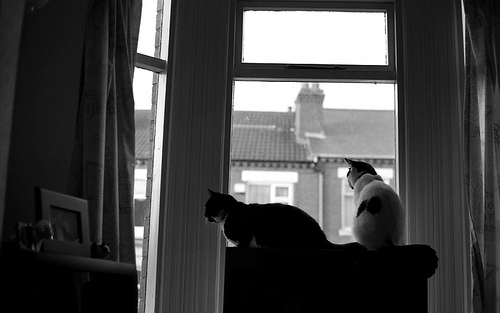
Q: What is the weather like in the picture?
A: It is overcast.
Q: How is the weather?
A: It is overcast.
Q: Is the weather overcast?
A: Yes, it is overcast.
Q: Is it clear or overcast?
A: It is overcast.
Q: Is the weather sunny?
A: No, it is overcast.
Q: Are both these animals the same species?
A: Yes, all the animals are cats.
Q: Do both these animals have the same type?
A: Yes, all the animals are cats.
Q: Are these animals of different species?
A: No, all the animals are cats.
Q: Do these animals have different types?
A: No, all the animals are cats.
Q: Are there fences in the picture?
A: No, there are no fences.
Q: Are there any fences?
A: No, there are no fences.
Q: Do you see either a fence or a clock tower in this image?
A: No, there are no fences or clock towers.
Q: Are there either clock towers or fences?
A: No, there are no fences or clock towers.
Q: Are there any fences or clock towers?
A: No, there are no fences or clock towers.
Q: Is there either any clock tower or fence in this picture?
A: No, there are no fences or clock towers.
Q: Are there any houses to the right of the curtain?
A: Yes, there is a house to the right of the curtain.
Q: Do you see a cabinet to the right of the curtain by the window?
A: No, there is a house to the right of the curtain.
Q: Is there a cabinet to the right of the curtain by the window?
A: No, there is a house to the right of the curtain.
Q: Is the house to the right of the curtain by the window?
A: Yes, the house is to the right of the curtain.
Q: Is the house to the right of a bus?
A: No, the house is to the right of the curtain.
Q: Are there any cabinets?
A: No, there are no cabinets.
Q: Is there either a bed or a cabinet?
A: No, there are no cabinets or beds.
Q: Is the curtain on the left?
A: Yes, the curtain is on the left of the image.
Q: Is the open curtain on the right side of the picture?
A: No, the curtain is on the left of the image.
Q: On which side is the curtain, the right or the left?
A: The curtain is on the left of the image.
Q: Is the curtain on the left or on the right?
A: The curtain is on the left of the image.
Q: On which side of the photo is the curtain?
A: The curtain is on the left of the image.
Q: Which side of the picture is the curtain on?
A: The curtain is on the left of the image.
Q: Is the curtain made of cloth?
A: Yes, the curtain is made of cloth.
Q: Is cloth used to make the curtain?
A: Yes, the curtain is made of cloth.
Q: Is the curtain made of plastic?
A: No, the curtain is made of cloth.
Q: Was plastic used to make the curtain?
A: No, the curtain is made of cloth.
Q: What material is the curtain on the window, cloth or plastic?
A: The curtain is made of cloth.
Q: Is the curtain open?
A: Yes, the curtain is open.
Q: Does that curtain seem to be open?
A: Yes, the curtain is open.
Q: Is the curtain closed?
A: No, the curtain is open.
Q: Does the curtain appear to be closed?
A: No, the curtain is open.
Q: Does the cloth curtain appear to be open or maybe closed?
A: The curtain is open.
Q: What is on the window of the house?
A: The curtain is on the window.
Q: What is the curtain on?
A: The curtain is on the window.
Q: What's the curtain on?
A: The curtain is on the window.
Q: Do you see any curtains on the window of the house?
A: Yes, there is a curtain on the window.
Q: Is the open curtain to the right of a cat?
A: No, the curtain is to the left of a cat.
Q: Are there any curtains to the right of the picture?
A: Yes, there is a curtain to the right of the picture.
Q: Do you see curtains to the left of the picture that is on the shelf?
A: No, the curtain is to the right of the picture.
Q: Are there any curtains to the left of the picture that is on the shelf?
A: No, the curtain is to the right of the picture.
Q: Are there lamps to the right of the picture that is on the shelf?
A: No, there is a curtain to the right of the picture.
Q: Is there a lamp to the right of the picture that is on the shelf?
A: No, there is a curtain to the right of the picture.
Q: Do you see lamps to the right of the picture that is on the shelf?
A: No, there is a curtain to the right of the picture.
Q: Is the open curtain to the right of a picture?
A: Yes, the curtain is to the right of a picture.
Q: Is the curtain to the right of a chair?
A: No, the curtain is to the right of a picture.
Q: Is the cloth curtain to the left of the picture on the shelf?
A: No, the curtain is to the right of the picture.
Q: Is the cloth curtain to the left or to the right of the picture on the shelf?
A: The curtain is to the right of the picture.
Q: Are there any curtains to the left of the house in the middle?
A: Yes, there is a curtain to the left of the house.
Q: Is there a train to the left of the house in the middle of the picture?
A: No, there is a curtain to the left of the house.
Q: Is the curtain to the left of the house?
A: Yes, the curtain is to the left of the house.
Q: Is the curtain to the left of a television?
A: No, the curtain is to the left of the house.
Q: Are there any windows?
A: Yes, there is a window.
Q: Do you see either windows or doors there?
A: Yes, there is a window.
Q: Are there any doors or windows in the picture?
A: Yes, there is a window.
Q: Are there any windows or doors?
A: Yes, there is a window.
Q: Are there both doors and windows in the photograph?
A: No, there is a window but no doors.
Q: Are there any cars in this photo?
A: No, there are no cars.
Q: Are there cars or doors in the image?
A: No, there are no cars or doors.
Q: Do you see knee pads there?
A: No, there are no knee pads.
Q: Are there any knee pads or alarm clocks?
A: No, there are no knee pads or alarm clocks.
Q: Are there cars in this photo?
A: No, there are no cars.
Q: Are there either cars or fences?
A: No, there are no cars or fences.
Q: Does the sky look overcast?
A: Yes, the sky is overcast.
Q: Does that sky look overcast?
A: Yes, the sky is overcast.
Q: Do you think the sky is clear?
A: No, the sky is overcast.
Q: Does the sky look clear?
A: No, the sky is overcast.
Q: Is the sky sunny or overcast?
A: The sky is overcast.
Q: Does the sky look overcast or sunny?
A: The sky is overcast.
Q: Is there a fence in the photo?
A: No, there are no fences.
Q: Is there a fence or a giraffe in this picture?
A: No, there are no fences or giraffes.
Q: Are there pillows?
A: No, there are no pillows.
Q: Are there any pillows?
A: No, there are no pillows.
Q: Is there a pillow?
A: No, there are no pillows.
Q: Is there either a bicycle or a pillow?
A: No, there are no pillows or bicycles.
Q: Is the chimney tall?
A: Yes, the chimney is tall.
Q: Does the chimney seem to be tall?
A: Yes, the chimney is tall.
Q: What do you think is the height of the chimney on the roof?
A: The chimney is tall.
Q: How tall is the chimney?
A: The chimney is tall.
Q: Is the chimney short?
A: No, the chimney is tall.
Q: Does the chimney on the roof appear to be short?
A: No, the chimney is tall.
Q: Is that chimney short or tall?
A: The chimney is tall.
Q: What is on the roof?
A: The chimney is on the roof.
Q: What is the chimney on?
A: The chimney is on the roof.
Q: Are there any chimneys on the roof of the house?
A: Yes, there is a chimney on the roof.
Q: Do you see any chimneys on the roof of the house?
A: Yes, there is a chimney on the roof.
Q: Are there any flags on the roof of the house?
A: No, there is a chimney on the roof.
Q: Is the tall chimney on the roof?
A: Yes, the chimney is on the roof.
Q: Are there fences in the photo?
A: No, there are no fences.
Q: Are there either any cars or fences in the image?
A: No, there are no fences or cars.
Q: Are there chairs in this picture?
A: No, there are no chairs.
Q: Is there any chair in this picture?
A: No, there are no chairs.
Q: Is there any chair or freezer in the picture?
A: No, there are no chairs or refrigerators.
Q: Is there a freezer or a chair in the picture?
A: No, there are no chairs or refrigerators.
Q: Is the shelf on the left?
A: Yes, the shelf is on the left of the image.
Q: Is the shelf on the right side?
A: No, the shelf is on the left of the image.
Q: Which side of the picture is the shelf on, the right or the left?
A: The shelf is on the left of the image.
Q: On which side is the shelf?
A: The shelf is on the left of the image.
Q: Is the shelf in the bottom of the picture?
A: Yes, the shelf is in the bottom of the image.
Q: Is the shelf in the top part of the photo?
A: No, the shelf is in the bottom of the image.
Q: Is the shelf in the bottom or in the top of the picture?
A: The shelf is in the bottom of the image.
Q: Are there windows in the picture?
A: Yes, there is a window.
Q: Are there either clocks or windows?
A: Yes, there is a window.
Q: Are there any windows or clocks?
A: Yes, there is a window.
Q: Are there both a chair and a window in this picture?
A: No, there is a window but no chairs.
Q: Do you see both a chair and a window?
A: No, there is a window but no chairs.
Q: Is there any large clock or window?
A: Yes, there is a large window.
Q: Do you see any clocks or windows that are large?
A: Yes, the window is large.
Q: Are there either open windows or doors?
A: Yes, there is an open window.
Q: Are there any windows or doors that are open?
A: Yes, the window is open.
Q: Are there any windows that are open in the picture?
A: Yes, there is an open window.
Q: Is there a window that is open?
A: Yes, there is a window that is open.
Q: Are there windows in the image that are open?
A: Yes, there is a window that is open.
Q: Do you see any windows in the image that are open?
A: Yes, there is a window that is open.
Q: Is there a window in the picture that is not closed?
A: Yes, there is a open window.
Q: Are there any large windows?
A: Yes, there is a large window.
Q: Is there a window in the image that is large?
A: Yes, there is a window that is large.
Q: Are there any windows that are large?
A: Yes, there is a window that is large.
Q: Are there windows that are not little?
A: Yes, there is a large window.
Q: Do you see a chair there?
A: No, there are no chairs.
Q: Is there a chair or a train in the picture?
A: No, there are no chairs or trains.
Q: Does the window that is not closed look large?
A: Yes, the window is large.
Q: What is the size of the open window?
A: The window is large.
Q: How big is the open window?
A: The window is large.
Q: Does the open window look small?
A: No, the window is large.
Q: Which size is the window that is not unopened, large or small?
A: The window is large.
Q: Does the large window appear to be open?
A: Yes, the window is open.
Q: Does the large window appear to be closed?
A: No, the window is open.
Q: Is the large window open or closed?
A: The window is open.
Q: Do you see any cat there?
A: Yes, there is a cat.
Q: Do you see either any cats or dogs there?
A: Yes, there is a cat.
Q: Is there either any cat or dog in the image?
A: Yes, there is a cat.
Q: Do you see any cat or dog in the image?
A: Yes, there is a cat.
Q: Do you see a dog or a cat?
A: Yes, there is a cat.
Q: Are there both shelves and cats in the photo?
A: Yes, there are both a cat and a shelf.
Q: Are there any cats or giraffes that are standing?
A: Yes, the cat is standing.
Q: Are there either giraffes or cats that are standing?
A: Yes, the cat is standing.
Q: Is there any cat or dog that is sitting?
A: Yes, the cat is sitting.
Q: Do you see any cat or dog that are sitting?
A: Yes, the cat is sitting.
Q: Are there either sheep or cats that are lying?
A: Yes, the cat is lying.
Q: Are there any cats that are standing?
A: Yes, there is a cat that is standing.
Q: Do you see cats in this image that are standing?
A: Yes, there is a cat that is standing.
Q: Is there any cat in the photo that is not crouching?
A: Yes, there is a cat that is standing.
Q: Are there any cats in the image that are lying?
A: Yes, there is a cat that is lying.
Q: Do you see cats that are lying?
A: Yes, there is a cat that is lying.